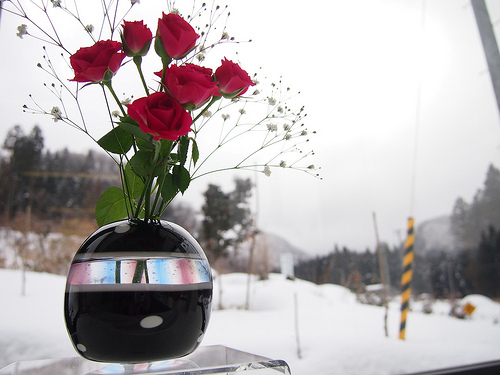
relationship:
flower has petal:
[68, 38, 127, 90] [89, 49, 114, 63]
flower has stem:
[71, 44, 146, 184] [107, 73, 133, 116]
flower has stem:
[68, 38, 127, 90] [107, 73, 133, 116]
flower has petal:
[71, 44, 146, 184] [89, 49, 114, 63]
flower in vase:
[68, 38, 127, 90] [72, 210, 199, 350]